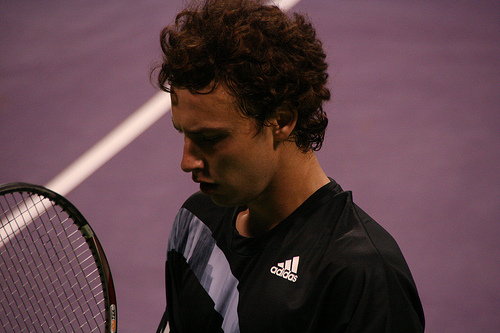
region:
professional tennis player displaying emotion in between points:
[0, 2, 495, 329]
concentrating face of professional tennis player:
[144, 3, 351, 210]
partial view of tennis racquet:
[0, 179, 120, 331]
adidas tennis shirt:
[157, 185, 429, 331]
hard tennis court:
[0, 0, 495, 330]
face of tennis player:
[170, 88, 284, 203]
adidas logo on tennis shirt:
[266, 251, 305, 286]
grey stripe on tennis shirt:
[164, 206, 239, 331]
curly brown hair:
[153, 2, 337, 147]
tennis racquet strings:
[0, 205, 67, 331]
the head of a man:
[146, 0, 331, 217]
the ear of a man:
[266, 90, 302, 145]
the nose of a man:
[173, 129, 208, 176]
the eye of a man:
[188, 121, 235, 154]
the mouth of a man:
[189, 168, 221, 197]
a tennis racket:
[0, 177, 134, 332]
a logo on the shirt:
[264, 250, 310, 288]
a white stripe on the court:
[0, 78, 172, 251]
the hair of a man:
[145, 5, 338, 157]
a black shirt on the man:
[158, 170, 425, 332]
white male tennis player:
[145, 2, 437, 332]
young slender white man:
[139, 3, 433, 332]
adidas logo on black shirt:
[264, 250, 306, 285]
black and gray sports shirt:
[157, 178, 439, 332]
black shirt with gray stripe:
[150, 171, 432, 331]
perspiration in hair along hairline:
[147, 52, 336, 159]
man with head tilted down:
[120, 3, 434, 332]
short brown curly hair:
[140, 0, 350, 151]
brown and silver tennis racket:
[1, 177, 126, 332]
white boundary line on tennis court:
[4, 1, 311, 244]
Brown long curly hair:
[145, 0, 327, 155]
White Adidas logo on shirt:
[267, 249, 301, 284]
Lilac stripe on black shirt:
[171, 205, 246, 331]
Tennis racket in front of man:
[0, 180, 116, 331]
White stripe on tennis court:
[0, 0, 297, 247]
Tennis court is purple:
[0, 0, 499, 332]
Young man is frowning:
[125, 0, 427, 332]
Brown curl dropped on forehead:
[142, 64, 180, 107]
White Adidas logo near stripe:
[265, 250, 304, 287]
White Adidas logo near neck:
[267, 253, 307, 287]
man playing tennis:
[2, 5, 434, 329]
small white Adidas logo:
[269, 252, 310, 284]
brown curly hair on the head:
[137, 6, 350, 161]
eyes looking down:
[161, 128, 237, 150]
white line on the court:
[2, 2, 307, 254]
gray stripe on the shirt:
[162, 213, 254, 329]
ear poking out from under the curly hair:
[267, 101, 308, 141]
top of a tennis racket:
[1, 173, 123, 331]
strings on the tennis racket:
[3, 193, 115, 332]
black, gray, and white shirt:
[150, 179, 442, 331]